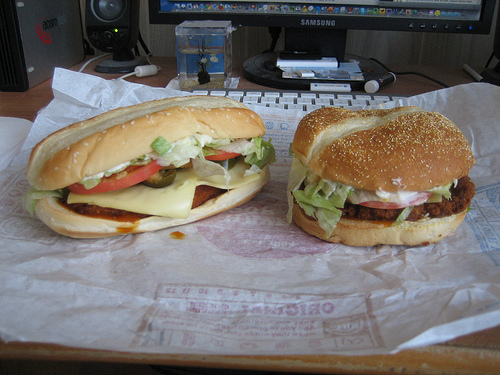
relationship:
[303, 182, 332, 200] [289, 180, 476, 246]
lettuce under bread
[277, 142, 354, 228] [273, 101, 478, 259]
lettuce under bun.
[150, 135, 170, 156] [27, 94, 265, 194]
lettuce under bread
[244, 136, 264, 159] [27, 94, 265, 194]
lettuce under bread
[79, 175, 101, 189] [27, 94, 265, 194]
lettuce under bread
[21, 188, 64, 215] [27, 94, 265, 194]
lettuce under bread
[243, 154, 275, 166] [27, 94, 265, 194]
lettuce under bread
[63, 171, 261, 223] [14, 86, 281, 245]
cheese on hamburger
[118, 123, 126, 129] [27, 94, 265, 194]
sesame seed on bread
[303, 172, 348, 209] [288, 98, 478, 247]
provolone sticking out of bn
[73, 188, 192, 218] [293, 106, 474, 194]
provolone sticking out of bread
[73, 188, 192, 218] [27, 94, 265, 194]
provolone sticking out of bread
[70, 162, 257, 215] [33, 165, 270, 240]
provolone sticking out of bread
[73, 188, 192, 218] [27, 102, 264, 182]
provolone sticking out of bun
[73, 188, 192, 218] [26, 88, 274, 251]
provolone sticking out of bun.